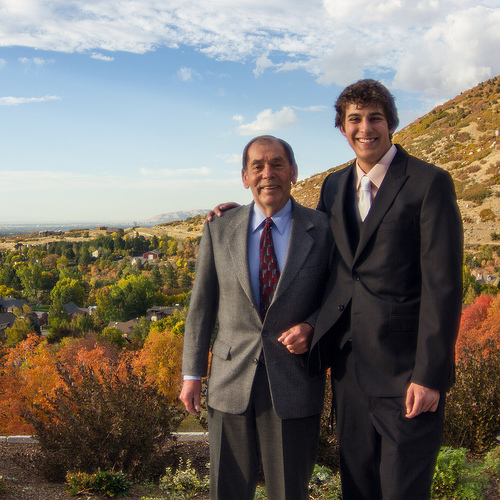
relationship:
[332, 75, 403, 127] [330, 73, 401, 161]
curly hair on head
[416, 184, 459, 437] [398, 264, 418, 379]
arm laying down by side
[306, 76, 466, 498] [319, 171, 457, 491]
man in suit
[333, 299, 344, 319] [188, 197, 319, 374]
button on jacket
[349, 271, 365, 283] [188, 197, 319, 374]
button on jacket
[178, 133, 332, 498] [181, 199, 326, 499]
man in suit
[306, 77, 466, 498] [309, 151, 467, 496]
man in suit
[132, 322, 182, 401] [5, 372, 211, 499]
tree on hill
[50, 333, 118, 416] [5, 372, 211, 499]
tree on hill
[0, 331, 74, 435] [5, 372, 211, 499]
tree on hill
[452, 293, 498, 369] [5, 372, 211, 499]
tree on hill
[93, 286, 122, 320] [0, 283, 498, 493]
tree on hill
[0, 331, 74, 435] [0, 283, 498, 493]
tree on hill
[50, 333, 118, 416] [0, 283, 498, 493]
tree on hill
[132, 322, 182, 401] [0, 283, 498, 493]
tree on hill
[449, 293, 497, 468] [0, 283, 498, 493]
tree on hill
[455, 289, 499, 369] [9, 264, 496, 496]
tree on hill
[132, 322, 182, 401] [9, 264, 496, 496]
tree on hill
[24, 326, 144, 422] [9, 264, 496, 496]
tree on hill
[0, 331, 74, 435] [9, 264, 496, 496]
tree on hill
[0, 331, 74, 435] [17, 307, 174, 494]
tree on hill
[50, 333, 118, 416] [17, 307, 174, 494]
tree on hill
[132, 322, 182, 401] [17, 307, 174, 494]
tree on hill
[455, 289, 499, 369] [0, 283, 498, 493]
tree on hill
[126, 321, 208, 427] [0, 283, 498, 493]
tree on hill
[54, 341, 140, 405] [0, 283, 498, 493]
tree on hill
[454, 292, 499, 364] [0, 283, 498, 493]
fall tree on hill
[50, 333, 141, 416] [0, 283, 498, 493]
tree on hill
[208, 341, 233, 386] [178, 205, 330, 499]
pocket on jacket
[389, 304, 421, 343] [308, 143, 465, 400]
pocket on black suit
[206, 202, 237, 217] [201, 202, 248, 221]
hand resting on shoulder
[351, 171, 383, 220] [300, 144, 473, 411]
tie hidden by jacket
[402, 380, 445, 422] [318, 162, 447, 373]
left hand coming out of black suit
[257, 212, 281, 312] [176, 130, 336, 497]
tie on man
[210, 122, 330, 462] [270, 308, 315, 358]
man has hand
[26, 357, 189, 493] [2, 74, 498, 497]
tree on hill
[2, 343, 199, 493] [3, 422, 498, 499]
tree on hill